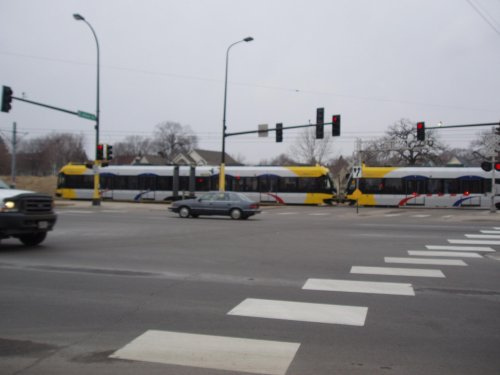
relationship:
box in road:
[229, 267, 399, 338] [19, 178, 496, 365]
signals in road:
[258, 108, 341, 142] [118, 213, 168, 260]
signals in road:
[256, 106, 366, 146] [6, 197, 498, 363]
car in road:
[153, 180, 254, 227] [63, 176, 433, 328]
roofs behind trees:
[101, 147, 235, 163] [108, 121, 198, 166]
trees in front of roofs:
[109, 113, 204, 157] [111, 147, 254, 165]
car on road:
[167, 191, 261, 220] [6, 197, 498, 363]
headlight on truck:
[5, 201, 13, 211] [1, 183, 57, 249]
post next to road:
[50, 13, 132, 186] [6, 197, 498, 363]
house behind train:
[132, 145, 250, 172] [44, 148, 499, 217]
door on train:
[408, 171, 433, 200] [51, 157, 499, 212]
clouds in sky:
[111, 20, 205, 84] [289, 23, 426, 68]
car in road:
[167, 191, 261, 220] [0, 199, 499, 374]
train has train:
[54, 164, 499, 210] [55, 160, 500, 209]